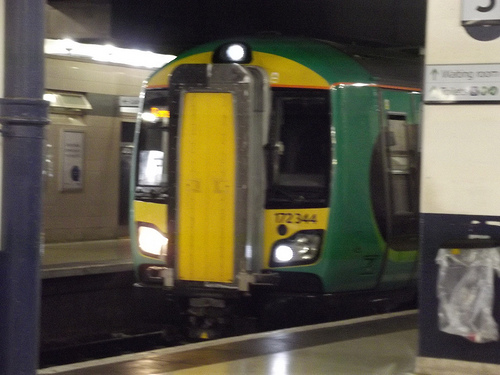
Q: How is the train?
A: Yellow and green.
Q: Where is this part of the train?
A: Front.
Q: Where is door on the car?
A: In front.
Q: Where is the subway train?
A: On the train trucks.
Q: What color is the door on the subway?
A: Yellow.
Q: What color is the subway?
A: Green.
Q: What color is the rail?
A: Gray.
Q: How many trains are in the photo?
A: One.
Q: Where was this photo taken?
A: Train station.